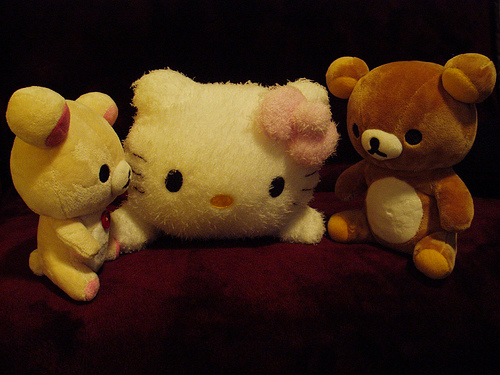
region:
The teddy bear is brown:
[319, 41, 499, 275]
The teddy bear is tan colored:
[2, 68, 132, 318]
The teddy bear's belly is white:
[358, 167, 428, 259]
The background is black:
[60, 9, 269, 63]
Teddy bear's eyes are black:
[348, 113, 432, 153]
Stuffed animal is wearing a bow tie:
[245, 72, 342, 173]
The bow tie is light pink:
[245, 75, 345, 180]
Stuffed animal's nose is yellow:
[205, 187, 242, 221]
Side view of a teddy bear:
[3, 83, 135, 307]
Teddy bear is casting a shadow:
[6, 226, 91, 309]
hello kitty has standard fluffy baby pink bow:
[250, 82, 341, 172]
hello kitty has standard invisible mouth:
[147, 211, 279, 241]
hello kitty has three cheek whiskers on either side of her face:
[125, 143, 320, 215]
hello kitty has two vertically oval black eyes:
[160, 162, 286, 207]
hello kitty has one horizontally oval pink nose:
[206, 191, 235, 209]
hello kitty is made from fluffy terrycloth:
[96, 61, 338, 254]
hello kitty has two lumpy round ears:
[125, 63, 332, 119]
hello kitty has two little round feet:
[105, 201, 327, 256]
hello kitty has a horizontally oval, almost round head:
[113, 78, 325, 245]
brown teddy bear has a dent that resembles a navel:
[381, 203, 394, 219]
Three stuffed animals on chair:
[12, 56, 472, 259]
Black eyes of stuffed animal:
[151, 146, 296, 207]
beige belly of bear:
[362, 173, 430, 245]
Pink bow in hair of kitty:
[246, 57, 335, 168]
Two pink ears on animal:
[5, 82, 135, 151]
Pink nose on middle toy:
[199, 190, 241, 211]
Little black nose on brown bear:
[362, 132, 395, 162]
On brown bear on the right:
[329, 50, 486, 271]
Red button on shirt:
[98, 212, 119, 227]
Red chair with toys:
[120, 254, 351, 347]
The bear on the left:
[1, 79, 135, 306]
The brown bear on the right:
[322, 49, 499, 279]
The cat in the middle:
[108, 63, 333, 255]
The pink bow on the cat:
[260, 84, 340, 171]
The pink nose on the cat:
[210, 192, 236, 212]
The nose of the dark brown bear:
[360, 128, 405, 160]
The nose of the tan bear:
[108, 156, 133, 198]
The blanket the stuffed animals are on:
[5, 213, 494, 373]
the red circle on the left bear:
[98, 209, 114, 230]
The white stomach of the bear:
[362, 173, 424, 246]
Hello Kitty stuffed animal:
[125, 54, 340, 256]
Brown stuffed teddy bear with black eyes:
[326, 48, 497, 298]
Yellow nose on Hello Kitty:
[200, 175, 252, 232]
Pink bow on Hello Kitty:
[251, 85, 344, 172]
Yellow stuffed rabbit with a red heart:
[1, 69, 139, 311]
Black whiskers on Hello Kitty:
[288, 156, 326, 242]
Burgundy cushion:
[132, 257, 375, 356]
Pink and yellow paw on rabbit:
[76, 270, 106, 304]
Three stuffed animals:
[6, 58, 488, 254]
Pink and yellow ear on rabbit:
[5, 84, 88, 174]